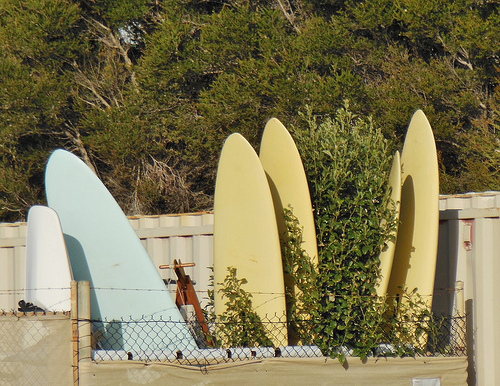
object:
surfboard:
[45, 149, 196, 359]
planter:
[70, 333, 472, 374]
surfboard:
[19, 204, 74, 313]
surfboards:
[215, 131, 290, 349]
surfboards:
[400, 102, 447, 344]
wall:
[4, 193, 498, 347]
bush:
[297, 104, 387, 351]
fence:
[0, 315, 477, 368]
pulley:
[159, 257, 215, 357]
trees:
[90, 4, 157, 217]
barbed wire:
[3, 284, 457, 299]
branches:
[85, 15, 146, 98]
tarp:
[77, 357, 468, 386]